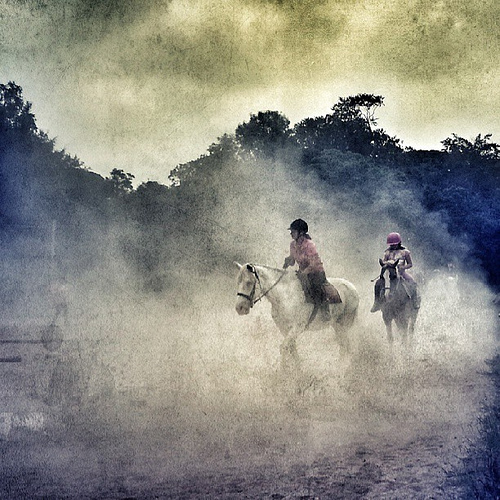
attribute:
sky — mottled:
[91, 32, 234, 89]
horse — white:
[228, 260, 365, 385]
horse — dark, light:
[369, 257, 421, 349]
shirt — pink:
[288, 234, 322, 284]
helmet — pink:
[385, 232, 402, 245]